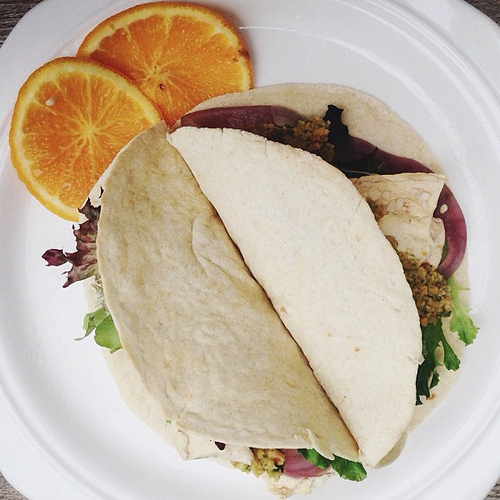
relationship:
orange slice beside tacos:
[13, 63, 164, 219] [74, 80, 464, 492]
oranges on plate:
[9, 11, 272, 248] [1, 11, 497, 498]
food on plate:
[88, 64, 470, 421] [19, 164, 499, 484]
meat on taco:
[385, 236, 457, 327] [171, 82, 476, 467]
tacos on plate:
[107, 79, 455, 490] [1, 11, 497, 498]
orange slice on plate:
[81, 0, 254, 122] [249, 0, 421, 87]